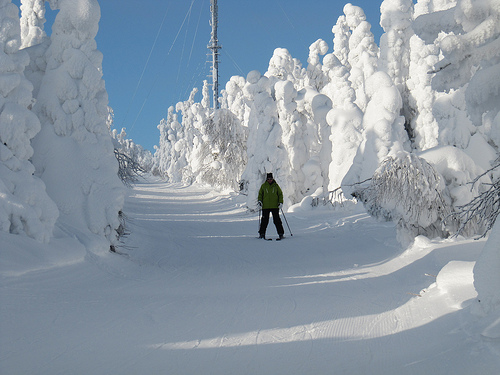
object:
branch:
[114, 147, 148, 188]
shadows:
[170, 237, 395, 339]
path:
[115, 173, 412, 374]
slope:
[101, 180, 267, 365]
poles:
[280, 208, 293, 236]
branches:
[354, 155, 497, 241]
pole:
[209, 2, 222, 114]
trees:
[154, 99, 237, 182]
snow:
[1, 1, 498, 373]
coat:
[258, 180, 284, 209]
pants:
[258, 207, 284, 237]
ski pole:
[259, 203, 262, 234]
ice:
[203, 2, 223, 109]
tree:
[319, 13, 356, 69]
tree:
[304, 30, 329, 89]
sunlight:
[222, 0, 433, 203]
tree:
[19, 1, 55, 101]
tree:
[262, 40, 311, 84]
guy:
[255, 172, 285, 241]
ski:
[256, 237, 273, 241]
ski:
[275, 237, 286, 241]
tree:
[240, 70, 292, 205]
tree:
[317, 45, 363, 202]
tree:
[376, 0, 415, 110]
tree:
[34, 1, 123, 244]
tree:
[2, 1, 58, 237]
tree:
[312, 53, 365, 201]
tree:
[339, 5, 412, 178]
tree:
[330, 12, 352, 62]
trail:
[0, 173, 499, 373]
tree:
[415, 5, 497, 236]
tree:
[269, 75, 313, 200]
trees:
[360, 152, 488, 228]